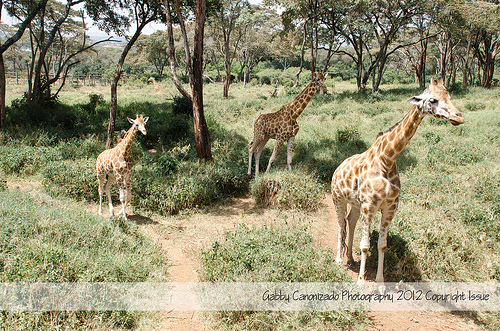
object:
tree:
[0, 0, 49, 117]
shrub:
[191, 221, 377, 331]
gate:
[4, 71, 124, 86]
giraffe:
[94, 113, 150, 221]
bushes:
[246, 165, 328, 211]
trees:
[386, 13, 429, 93]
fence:
[4, 70, 129, 89]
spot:
[383, 215, 391, 223]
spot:
[339, 169, 348, 180]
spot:
[362, 225, 370, 233]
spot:
[343, 170, 351, 190]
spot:
[344, 188, 352, 198]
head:
[125, 112, 149, 136]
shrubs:
[0, 180, 173, 331]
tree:
[0, 0, 122, 101]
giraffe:
[145, 77, 163, 98]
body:
[329, 107, 421, 292]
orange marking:
[371, 178, 386, 193]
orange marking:
[367, 148, 377, 162]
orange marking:
[381, 143, 395, 158]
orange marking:
[401, 113, 412, 128]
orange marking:
[401, 118, 414, 139]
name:
[261, 289, 339, 302]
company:
[255, 284, 396, 311]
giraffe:
[328, 76, 464, 288]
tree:
[183, 1, 261, 99]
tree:
[84, 0, 189, 151]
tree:
[476, 0, 498, 89]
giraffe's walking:
[329, 76, 464, 291]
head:
[404, 76, 465, 127]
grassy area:
[0, 33, 498, 330]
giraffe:
[246, 72, 329, 180]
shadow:
[0, 92, 195, 152]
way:
[0, 177, 485, 331]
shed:
[21, 45, 36, 54]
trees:
[278, 3, 314, 90]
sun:
[0, 0, 499, 330]